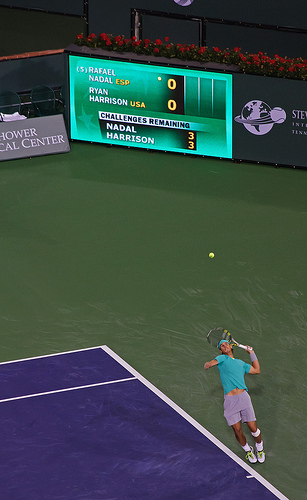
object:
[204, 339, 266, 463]
man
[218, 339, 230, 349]
headband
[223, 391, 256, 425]
shorts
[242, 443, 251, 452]
socks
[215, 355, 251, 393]
t-shirt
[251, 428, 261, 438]
leg wrap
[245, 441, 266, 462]
shoes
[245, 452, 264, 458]
laces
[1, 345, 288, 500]
tennis court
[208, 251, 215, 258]
tennis ball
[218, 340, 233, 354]
head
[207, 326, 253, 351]
racket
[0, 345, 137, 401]
lines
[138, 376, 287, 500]
line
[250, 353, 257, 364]
band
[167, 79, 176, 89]
number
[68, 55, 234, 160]
board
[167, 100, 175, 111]
number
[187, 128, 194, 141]
number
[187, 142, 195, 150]
number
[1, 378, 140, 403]
line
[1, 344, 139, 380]
edge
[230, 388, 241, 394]
belly button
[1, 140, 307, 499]
exterior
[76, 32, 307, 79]
flowers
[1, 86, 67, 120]
objects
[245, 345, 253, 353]
hand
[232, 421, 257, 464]
legs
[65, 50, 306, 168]
wall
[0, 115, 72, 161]
sign